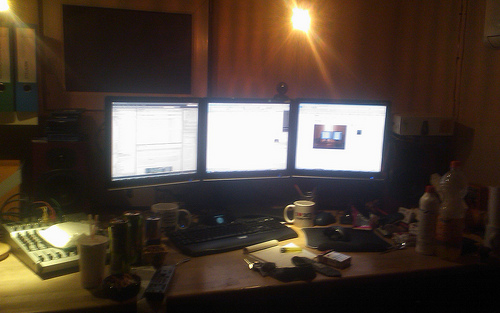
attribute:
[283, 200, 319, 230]
mug — white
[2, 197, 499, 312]
desk — full, cluttered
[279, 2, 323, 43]
light — on, yellow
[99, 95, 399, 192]
monitors — on, attached, turned on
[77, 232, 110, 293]
cup — white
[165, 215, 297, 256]
keyboard — black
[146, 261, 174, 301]
remote control — black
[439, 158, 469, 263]
bottle — big